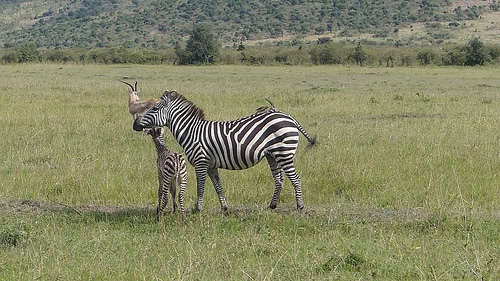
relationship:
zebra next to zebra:
[148, 127, 189, 215] [131, 87, 320, 211]